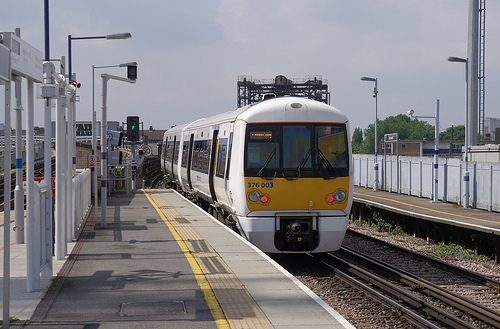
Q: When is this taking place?
A: Daytime.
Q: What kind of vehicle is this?
A: Train.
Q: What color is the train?
A: Yellow and white.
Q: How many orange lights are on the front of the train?
A: Two.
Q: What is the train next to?
A: Platform.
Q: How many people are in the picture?
A: None.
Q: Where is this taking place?
A: On the train tracks at a pick up spot.